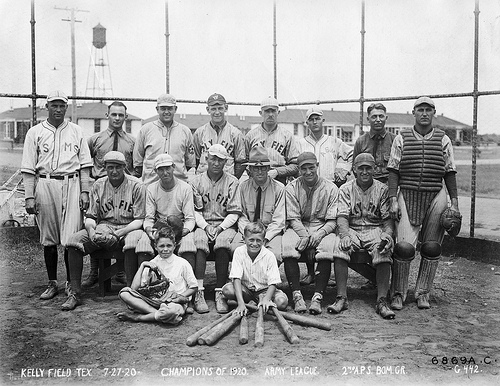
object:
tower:
[87, 23, 115, 106]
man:
[239, 157, 285, 304]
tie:
[254, 186, 261, 221]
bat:
[257, 307, 264, 347]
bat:
[268, 309, 303, 346]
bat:
[238, 317, 250, 347]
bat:
[271, 296, 332, 335]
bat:
[205, 310, 238, 347]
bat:
[185, 301, 233, 346]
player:
[397, 98, 461, 310]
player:
[24, 95, 93, 307]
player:
[91, 148, 147, 297]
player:
[142, 152, 196, 292]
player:
[138, 99, 200, 181]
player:
[193, 96, 247, 177]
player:
[246, 103, 288, 172]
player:
[293, 112, 356, 188]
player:
[281, 158, 337, 312]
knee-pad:
[421, 240, 442, 261]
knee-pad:
[389, 243, 417, 262]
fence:
[2, 0, 499, 261]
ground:
[4, 230, 499, 384]